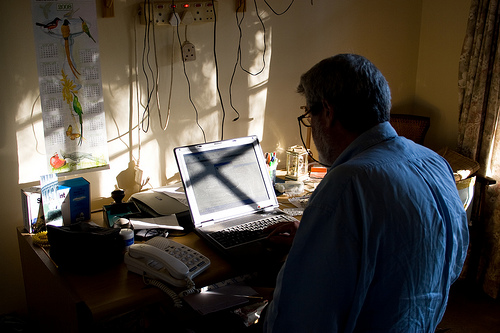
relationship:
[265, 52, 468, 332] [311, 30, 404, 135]
man has hair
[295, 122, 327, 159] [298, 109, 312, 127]
strap hangs from eyeglasses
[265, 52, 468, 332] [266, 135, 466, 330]
man wears shirt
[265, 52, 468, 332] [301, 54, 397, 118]
man has hair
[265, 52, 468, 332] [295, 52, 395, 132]
man has head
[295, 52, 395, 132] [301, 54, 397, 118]
head has hair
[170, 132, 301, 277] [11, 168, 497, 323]
laptop on desk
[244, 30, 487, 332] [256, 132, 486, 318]
man wears collared shirt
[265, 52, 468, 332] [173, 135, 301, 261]
man holding laptop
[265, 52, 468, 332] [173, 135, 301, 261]
man in front of laptop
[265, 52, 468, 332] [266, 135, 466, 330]
man wearing a shirt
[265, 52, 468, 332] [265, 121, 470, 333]
man wearing a collared shirt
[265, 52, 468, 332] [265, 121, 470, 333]
man on back of collared shirt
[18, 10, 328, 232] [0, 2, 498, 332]
sunshine in room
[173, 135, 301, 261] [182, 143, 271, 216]
laptop has a screen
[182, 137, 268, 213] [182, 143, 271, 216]
shadow on screen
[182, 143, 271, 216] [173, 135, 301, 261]
screen on laptop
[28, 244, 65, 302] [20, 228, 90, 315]
pencil wedged in corner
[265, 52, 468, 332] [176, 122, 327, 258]
man sitting at laptop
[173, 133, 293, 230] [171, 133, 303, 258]
light shining on laptop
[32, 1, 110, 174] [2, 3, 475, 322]
calendar on wall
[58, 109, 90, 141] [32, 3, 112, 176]
butterfly on calendar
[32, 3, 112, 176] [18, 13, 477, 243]
calendar on wall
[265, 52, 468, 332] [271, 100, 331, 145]
man wearing eyeglasses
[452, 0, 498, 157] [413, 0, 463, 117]
curtains on wall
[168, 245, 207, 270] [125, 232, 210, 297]
big button on telephone